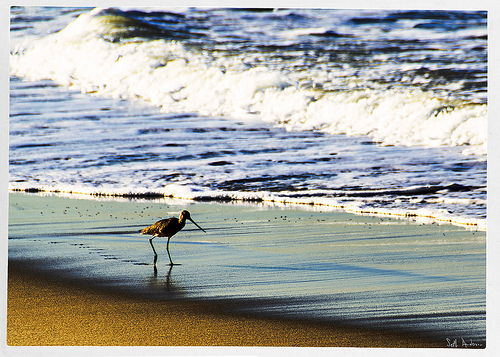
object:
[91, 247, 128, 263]
footprints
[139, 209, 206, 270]
bird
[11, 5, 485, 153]
wave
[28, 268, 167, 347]
sand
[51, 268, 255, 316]
shoreline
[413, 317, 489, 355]
signature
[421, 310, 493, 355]
right corner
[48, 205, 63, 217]
pebbles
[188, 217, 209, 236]
beak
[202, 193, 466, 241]
ground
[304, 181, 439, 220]
previous waves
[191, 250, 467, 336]
beach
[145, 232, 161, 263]
leg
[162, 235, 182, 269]
leg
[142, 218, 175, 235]
feathers